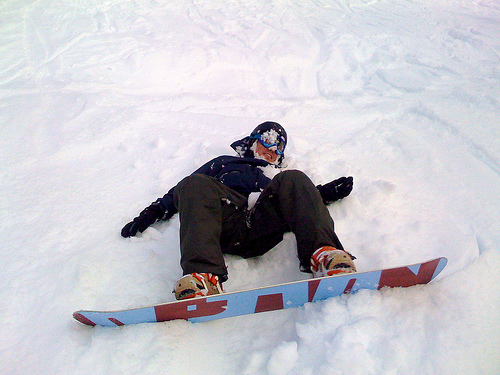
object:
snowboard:
[71, 256, 447, 326]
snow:
[0, 0, 498, 373]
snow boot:
[172, 272, 226, 300]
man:
[119, 121, 357, 302]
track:
[380, 102, 499, 249]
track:
[4, 75, 397, 115]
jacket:
[158, 157, 286, 219]